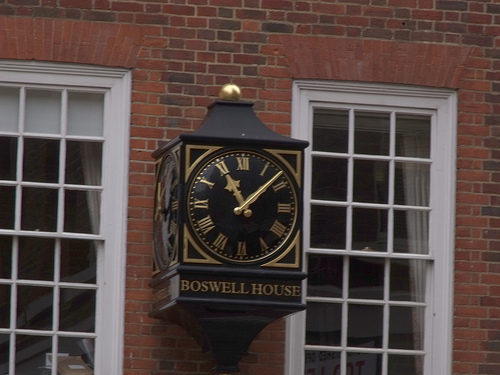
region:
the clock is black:
[167, 149, 318, 289]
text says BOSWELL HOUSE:
[170, 270, 325, 305]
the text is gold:
[186, 278, 331, 310]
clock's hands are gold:
[183, 152, 300, 242]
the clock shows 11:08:
[200, 146, 297, 276]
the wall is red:
[132, 57, 192, 120]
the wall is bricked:
[125, 62, 201, 145]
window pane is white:
[276, 76, 472, 363]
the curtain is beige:
[398, 165, 430, 275]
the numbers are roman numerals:
[186, 159, 318, 278]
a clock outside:
[82, 52, 351, 368]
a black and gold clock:
[86, 20, 378, 371]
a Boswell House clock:
[74, 42, 363, 334]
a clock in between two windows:
[14, 43, 407, 373]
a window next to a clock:
[142, 32, 444, 369]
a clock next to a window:
[158, 35, 471, 347]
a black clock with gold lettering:
[127, 30, 333, 367]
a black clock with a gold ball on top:
[64, 64, 352, 372]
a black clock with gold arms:
[104, 60, 373, 370]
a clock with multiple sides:
[78, 28, 383, 361]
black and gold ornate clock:
[137, 61, 321, 364]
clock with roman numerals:
[170, 143, 313, 263]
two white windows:
[6, 43, 466, 370]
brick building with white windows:
[12, 24, 467, 365]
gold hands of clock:
[217, 155, 292, 232]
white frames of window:
[421, 83, 478, 373]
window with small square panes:
[272, 64, 497, 372]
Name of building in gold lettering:
[165, 268, 307, 307]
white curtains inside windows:
[400, 112, 437, 357]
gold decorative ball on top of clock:
[215, 74, 259, 111]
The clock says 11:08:
[156, 123, 328, 319]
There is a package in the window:
[43, 333, 87, 374]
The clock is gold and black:
[178, 133, 323, 283]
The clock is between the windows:
[3, 54, 472, 374]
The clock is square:
[146, 109, 316, 322]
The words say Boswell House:
[173, 271, 311, 311]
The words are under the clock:
[156, 118, 314, 328]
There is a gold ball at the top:
[211, 81, 256, 102]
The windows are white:
[1, 52, 464, 370]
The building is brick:
[10, 0, 499, 373]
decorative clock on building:
[137, 77, 317, 352]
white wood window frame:
[292, 71, 390, 118]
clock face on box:
[180, 159, 297, 263]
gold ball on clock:
[213, 75, 255, 110]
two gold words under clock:
[177, 243, 316, 310]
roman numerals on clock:
[201, 203, 237, 253]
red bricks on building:
[163, 42, 254, 77]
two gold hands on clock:
[224, 167, 289, 223]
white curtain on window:
[398, 126, 438, 310]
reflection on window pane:
[57, 289, 91, 324]